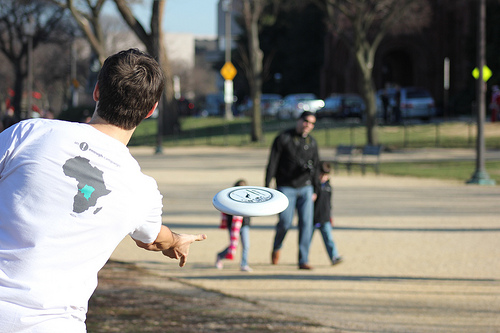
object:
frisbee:
[216, 181, 281, 218]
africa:
[60, 156, 105, 219]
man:
[3, 43, 192, 332]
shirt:
[2, 121, 129, 320]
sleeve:
[142, 188, 156, 244]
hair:
[101, 58, 148, 119]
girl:
[220, 184, 258, 271]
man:
[269, 112, 311, 270]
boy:
[317, 161, 341, 261]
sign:
[218, 60, 237, 82]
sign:
[471, 66, 492, 79]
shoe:
[273, 251, 279, 265]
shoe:
[299, 260, 315, 270]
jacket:
[281, 138, 314, 187]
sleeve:
[262, 139, 282, 180]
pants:
[279, 186, 310, 257]